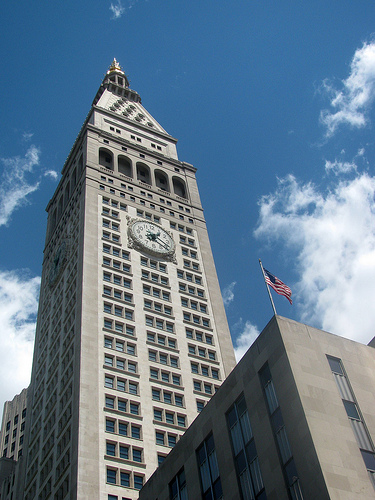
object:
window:
[102, 196, 111, 209]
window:
[100, 144, 115, 170]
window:
[103, 334, 115, 350]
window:
[116, 337, 125, 355]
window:
[125, 339, 136, 354]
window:
[148, 348, 160, 366]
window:
[158, 349, 173, 366]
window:
[102, 218, 111, 229]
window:
[113, 301, 130, 320]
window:
[124, 357, 142, 379]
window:
[104, 437, 119, 459]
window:
[102, 370, 117, 389]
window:
[132, 422, 144, 441]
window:
[153, 385, 164, 403]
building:
[16, 56, 239, 498]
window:
[125, 322, 139, 340]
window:
[102, 217, 111, 227]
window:
[143, 283, 153, 298]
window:
[179, 296, 192, 311]